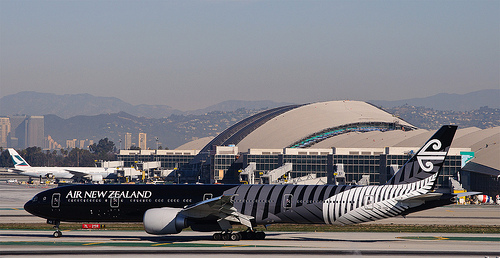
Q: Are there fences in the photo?
A: No, there are no fences.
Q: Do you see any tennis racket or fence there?
A: No, there are no fences or rackets.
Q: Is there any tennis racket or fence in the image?
A: No, there are no fences or rackets.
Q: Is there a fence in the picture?
A: No, there are no fences.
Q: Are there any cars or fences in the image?
A: No, there are no fences or cars.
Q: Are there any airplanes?
A: Yes, there is an airplane.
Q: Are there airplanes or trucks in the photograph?
A: Yes, there is an airplane.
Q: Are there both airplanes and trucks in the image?
A: No, there is an airplane but no trucks.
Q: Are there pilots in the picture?
A: No, there are no pilots.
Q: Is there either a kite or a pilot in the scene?
A: No, there are no pilots or kites.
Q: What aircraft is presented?
A: The aircraft is an airplane.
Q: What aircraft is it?
A: The aircraft is an airplane.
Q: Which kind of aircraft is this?
A: That is an airplane.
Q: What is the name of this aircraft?
A: That is an airplane.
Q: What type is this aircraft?
A: That is an airplane.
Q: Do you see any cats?
A: No, there are no cats.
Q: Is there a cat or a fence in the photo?
A: No, there are no cats or fences.